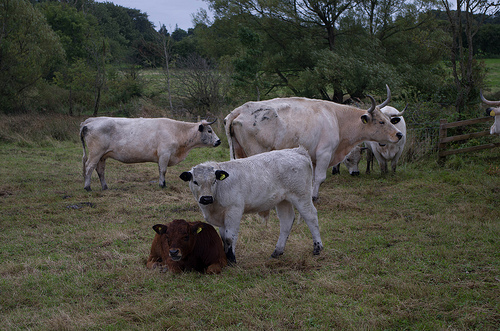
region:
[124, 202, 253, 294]
the cow is brown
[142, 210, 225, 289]
the cow is resting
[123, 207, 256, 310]
the cow is resting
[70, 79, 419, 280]
a lot of cows in the pasture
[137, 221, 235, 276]
one brown cow laying down in the pasture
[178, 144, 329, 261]
one white cow behind the brown cow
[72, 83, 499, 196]
four cows with horns in the back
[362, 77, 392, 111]
cows horns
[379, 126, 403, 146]
cow nose and mouth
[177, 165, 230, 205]
cow head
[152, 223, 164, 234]
brown cow ears in the front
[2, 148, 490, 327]
lot of grass in the field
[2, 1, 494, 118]
a lot of trees in the background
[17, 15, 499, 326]
Picture taken indoors.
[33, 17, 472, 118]
Picture taken during the outdoors.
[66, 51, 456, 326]
Various cows on the pasture.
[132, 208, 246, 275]
One brown cow.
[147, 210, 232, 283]
Brown cow is laying on the ground.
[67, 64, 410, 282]
The cows are looking in various positions.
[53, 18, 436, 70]
Tall trees in the background.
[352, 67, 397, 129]
The cow has long horns.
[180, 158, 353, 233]
Small baby cow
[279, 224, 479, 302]
the grass is cut short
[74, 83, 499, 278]
group of cloven hoofed animals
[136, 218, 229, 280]
brown animal sitting on grass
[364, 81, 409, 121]
horns of male animal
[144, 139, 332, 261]
animal next to brown animal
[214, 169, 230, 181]
black ear of animal with yellow inside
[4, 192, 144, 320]
green and brown grass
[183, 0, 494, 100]
green trees in the background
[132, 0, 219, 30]
cloudy sky in background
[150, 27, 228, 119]
dead tree behind animals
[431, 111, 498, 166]
part of wooden fence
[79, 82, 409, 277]
Group of white and brown cows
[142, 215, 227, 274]
brown cow lying down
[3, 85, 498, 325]
field with brown and white cows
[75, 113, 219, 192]
white cow standing up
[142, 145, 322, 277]
one brown cow and one white cow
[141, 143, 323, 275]
the brown cow is on the left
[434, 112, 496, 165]
slatted wooden fencing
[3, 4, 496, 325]
cows in a large field in front of trees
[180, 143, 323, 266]
white cow with a black nose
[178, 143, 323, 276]
white cow with black ears